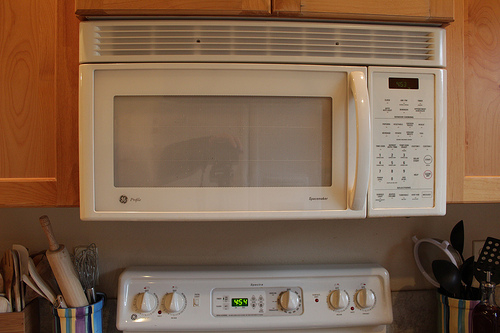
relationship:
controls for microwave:
[374, 96, 434, 208] [77, 16, 448, 222]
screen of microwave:
[113, 95, 334, 189] [77, 16, 448, 222]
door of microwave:
[78, 63, 366, 220] [77, 16, 448, 222]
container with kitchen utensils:
[52, 290, 104, 332] [21, 211, 100, 307]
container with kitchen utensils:
[436, 288, 483, 332] [408, 220, 500, 301]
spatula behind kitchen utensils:
[28, 254, 60, 305] [39, 215, 89, 307]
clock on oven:
[230, 296, 250, 307] [114, 266, 394, 332]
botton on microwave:
[423, 153, 435, 165] [77, 16, 448, 222]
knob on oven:
[279, 288, 299, 311] [114, 266, 394, 332]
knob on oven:
[328, 290, 348, 309] [114, 266, 394, 332]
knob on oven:
[163, 291, 185, 313] [114, 266, 394, 332]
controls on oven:
[135, 291, 159, 313] [114, 266, 394, 332]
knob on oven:
[357, 288, 374, 307] [114, 266, 394, 332]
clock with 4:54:
[230, 296, 250, 307] [234, 297, 247, 305]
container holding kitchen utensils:
[52, 290, 104, 332] [21, 211, 100, 307]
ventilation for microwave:
[79, 20, 448, 67] [77, 16, 448, 222]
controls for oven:
[131, 287, 377, 318] [114, 266, 394, 332]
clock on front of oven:
[230, 296, 250, 307] [114, 266, 394, 332]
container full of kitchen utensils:
[52, 290, 104, 332] [21, 211, 100, 307]